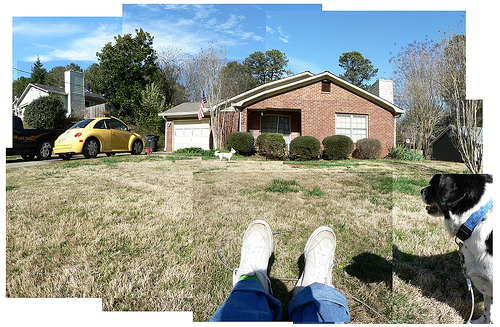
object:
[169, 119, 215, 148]
door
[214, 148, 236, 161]
white dog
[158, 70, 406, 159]
house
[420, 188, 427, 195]
nose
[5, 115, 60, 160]
truck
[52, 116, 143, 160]
beetle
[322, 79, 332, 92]
vents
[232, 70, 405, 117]
attic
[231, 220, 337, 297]
shoes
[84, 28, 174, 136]
tree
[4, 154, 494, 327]
field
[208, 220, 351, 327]
person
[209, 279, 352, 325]
blue pants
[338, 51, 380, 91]
ground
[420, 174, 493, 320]
dog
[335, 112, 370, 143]
window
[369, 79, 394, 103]
chimney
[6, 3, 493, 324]
scene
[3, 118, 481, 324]
yard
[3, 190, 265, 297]
grass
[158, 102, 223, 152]
garage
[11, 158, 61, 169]
driveway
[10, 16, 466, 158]
background